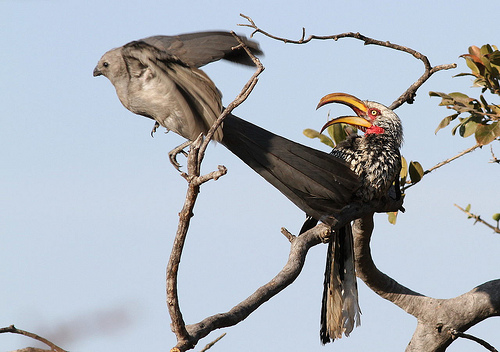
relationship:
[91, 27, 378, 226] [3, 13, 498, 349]
bird perched on tree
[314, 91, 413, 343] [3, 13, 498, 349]
bird perched on tree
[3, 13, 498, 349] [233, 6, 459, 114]
tree has branch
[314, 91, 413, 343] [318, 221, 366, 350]
bird has tail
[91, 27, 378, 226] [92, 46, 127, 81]
bird has head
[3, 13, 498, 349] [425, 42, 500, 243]
tree has leaves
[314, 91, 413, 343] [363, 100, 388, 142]
bird has face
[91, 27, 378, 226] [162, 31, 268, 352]
bird flying off branch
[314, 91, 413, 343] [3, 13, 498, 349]
bird perched in tree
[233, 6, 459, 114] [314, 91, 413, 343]
branch above bird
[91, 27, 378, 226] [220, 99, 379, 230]
bird has tail